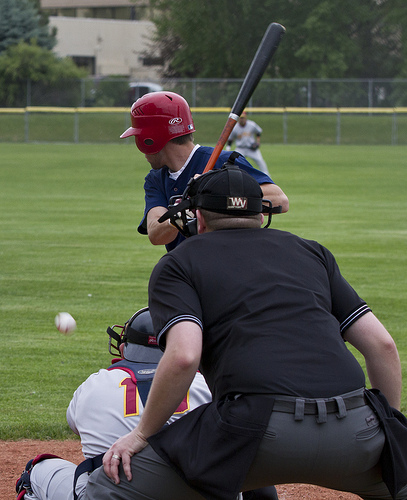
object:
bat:
[202, 21, 287, 175]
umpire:
[75, 165, 407, 500]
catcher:
[13, 303, 277, 499]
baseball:
[54, 310, 79, 334]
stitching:
[53, 308, 78, 336]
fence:
[0, 76, 407, 149]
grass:
[0, 141, 406, 440]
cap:
[192, 166, 265, 214]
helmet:
[121, 307, 166, 364]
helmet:
[118, 91, 196, 156]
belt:
[272, 389, 366, 416]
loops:
[294, 397, 306, 422]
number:
[119, 376, 140, 418]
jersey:
[65, 363, 210, 480]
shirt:
[145, 223, 372, 400]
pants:
[75, 388, 407, 500]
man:
[117, 88, 291, 257]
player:
[225, 110, 271, 177]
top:
[133, 145, 274, 244]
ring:
[111, 452, 120, 461]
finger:
[110, 452, 120, 484]